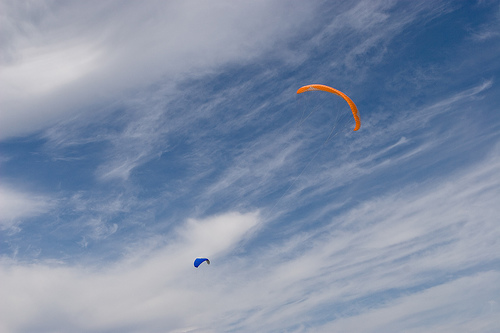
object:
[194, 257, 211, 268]
kite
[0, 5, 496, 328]
sky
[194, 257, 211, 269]
float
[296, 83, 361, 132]
kite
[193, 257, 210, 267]
sail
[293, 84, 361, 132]
sail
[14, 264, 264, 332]
cloud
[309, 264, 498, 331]
cloud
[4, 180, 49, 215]
cloud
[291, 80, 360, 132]
object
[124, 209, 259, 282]
cloud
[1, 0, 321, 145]
cloud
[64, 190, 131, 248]
cloud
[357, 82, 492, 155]
cloud